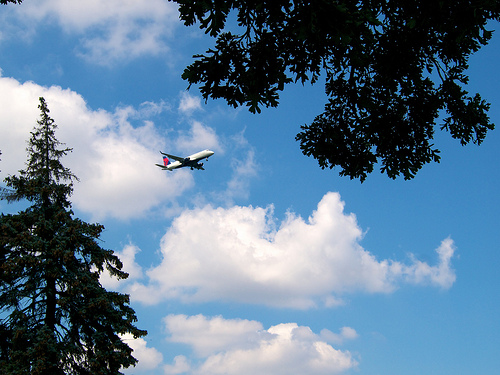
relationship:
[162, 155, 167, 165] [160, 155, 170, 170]
paint on tail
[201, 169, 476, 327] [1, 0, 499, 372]
cloud in sky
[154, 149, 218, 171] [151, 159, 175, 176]
airplane has tail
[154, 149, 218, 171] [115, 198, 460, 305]
airplane flying by cloud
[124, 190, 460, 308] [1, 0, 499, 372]
cloud in sky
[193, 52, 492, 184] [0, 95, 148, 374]
leaves of a pine tree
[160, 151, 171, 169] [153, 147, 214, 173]
tail of plane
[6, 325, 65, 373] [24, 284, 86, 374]
leaves on branches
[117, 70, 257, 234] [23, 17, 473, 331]
airplane in sky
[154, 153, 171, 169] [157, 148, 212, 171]
tail of plane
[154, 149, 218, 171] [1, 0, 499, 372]
airplane in sky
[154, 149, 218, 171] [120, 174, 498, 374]
airplane in sky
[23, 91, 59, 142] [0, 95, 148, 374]
top of pine tree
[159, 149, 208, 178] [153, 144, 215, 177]
wings on airplane